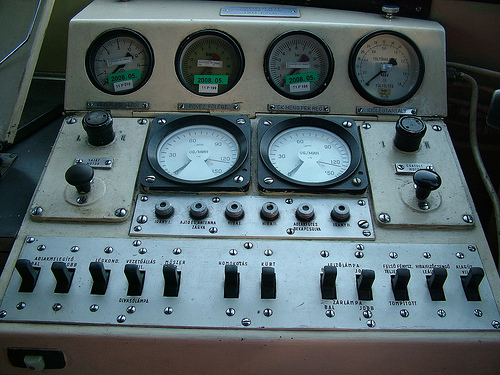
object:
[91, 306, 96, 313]
bolt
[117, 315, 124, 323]
bolt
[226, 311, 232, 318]
bolt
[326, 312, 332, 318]
bolt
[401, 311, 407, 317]
bolt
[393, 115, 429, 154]
knobs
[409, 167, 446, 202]
knobs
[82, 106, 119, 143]
knobs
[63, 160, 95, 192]
knobs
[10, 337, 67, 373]
button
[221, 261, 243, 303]
switches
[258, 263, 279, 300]
switches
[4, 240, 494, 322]
panel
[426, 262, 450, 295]
knobs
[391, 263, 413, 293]
knobs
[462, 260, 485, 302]
knobs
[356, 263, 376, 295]
knobs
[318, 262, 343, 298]
knobs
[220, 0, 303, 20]
panel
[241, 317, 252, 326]
screw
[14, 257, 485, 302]
row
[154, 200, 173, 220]
indicator lights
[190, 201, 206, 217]
indicator lights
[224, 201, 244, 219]
indicator lights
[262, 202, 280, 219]
indicator lights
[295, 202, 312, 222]
indicator lights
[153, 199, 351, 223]
row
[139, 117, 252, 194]
dial instruments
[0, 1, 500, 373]
console center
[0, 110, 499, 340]
control panel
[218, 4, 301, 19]
label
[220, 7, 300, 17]
plate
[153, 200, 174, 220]
audio jacks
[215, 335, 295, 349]
specks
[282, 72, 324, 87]
green sticker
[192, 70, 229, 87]
green sticker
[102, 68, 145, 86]
green sticker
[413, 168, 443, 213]
button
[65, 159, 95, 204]
button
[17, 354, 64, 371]
button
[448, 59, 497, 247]
electrical cord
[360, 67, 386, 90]
needle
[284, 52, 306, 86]
needle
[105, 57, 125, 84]
needle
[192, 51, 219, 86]
needle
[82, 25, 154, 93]
control gauge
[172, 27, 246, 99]
control gauge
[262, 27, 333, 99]
control gauge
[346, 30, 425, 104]
control gauge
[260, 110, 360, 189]
control gauge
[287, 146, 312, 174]
needle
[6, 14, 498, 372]
machine